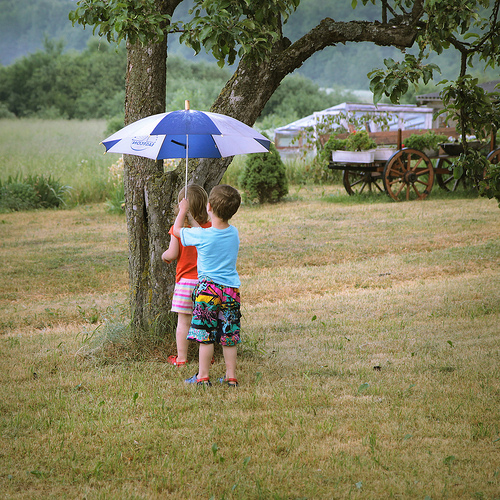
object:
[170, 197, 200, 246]
arm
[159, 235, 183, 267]
arm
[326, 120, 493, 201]
cart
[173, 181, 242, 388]
boy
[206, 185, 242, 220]
head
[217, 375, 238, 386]
feet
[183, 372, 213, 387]
sandles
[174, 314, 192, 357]
leg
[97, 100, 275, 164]
umbrella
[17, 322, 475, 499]
ground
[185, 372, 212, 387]
feet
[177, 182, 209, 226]
head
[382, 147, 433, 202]
wheel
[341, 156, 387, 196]
wheel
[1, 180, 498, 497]
grass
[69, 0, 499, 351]
tree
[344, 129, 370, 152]
plants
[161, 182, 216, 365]
girl